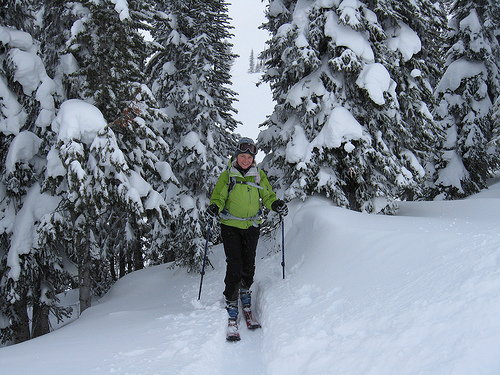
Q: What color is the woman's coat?
A: Green.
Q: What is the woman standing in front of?
A: Trees.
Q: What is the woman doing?
A: Skiing.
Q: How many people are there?
A: 1.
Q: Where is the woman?
A: She is outside.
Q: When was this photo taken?
A: During the day.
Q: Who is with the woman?
A: She is alone.